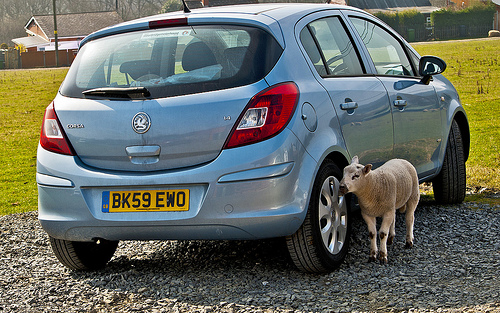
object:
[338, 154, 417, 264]
lamb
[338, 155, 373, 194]
head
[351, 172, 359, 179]
eye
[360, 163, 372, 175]
ear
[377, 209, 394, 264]
front leg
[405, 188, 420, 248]
hind leg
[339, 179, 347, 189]
nose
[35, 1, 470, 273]
car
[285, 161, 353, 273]
wheel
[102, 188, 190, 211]
license plate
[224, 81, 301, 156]
taillight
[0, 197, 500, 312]
gravel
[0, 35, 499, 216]
field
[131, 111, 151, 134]
logo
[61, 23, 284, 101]
back window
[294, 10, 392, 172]
door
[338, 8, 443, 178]
door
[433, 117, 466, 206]
front wheel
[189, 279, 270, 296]
rock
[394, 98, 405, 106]
handle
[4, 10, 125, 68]
house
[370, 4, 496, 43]
shrub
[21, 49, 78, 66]
fence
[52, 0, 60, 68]
pole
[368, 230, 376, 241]
smudge